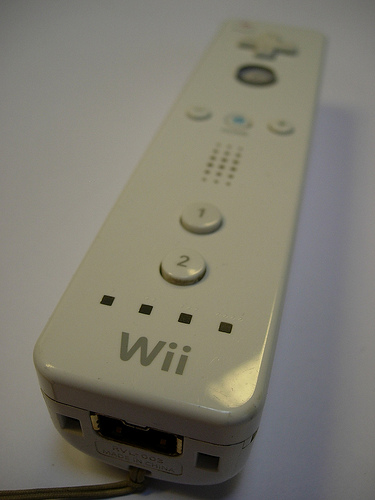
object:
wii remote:
[32, 17, 326, 487]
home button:
[235, 62, 275, 85]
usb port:
[88, 411, 184, 459]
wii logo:
[120, 331, 191, 375]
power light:
[100, 295, 115, 306]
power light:
[138, 303, 153, 315]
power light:
[178, 312, 192, 324]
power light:
[218, 321, 233, 334]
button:
[161, 246, 206, 285]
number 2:
[177, 254, 190, 267]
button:
[181, 201, 221, 234]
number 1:
[198, 207, 205, 217]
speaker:
[201, 141, 245, 188]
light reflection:
[206, 289, 278, 408]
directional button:
[237, 30, 296, 59]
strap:
[0, 467, 152, 497]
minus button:
[186, 105, 212, 121]